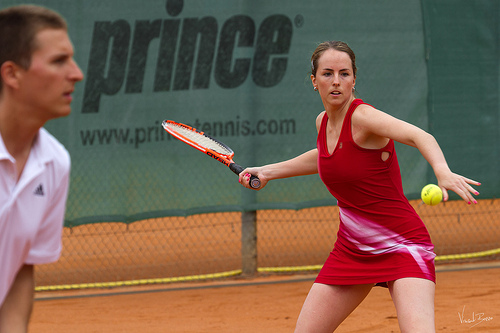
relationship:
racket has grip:
[161, 119, 260, 189] [229, 162, 260, 189]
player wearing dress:
[238, 42, 483, 333] [313, 99, 436, 286]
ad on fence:
[80, 0, 304, 144] [0, 1, 499, 228]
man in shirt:
[0, 4, 83, 332] [0, 127, 72, 308]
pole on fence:
[241, 211, 257, 279] [0, 1, 499, 228]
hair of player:
[311, 40, 357, 76] [238, 42, 483, 333]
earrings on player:
[313, 86, 318, 91] [238, 42, 483, 333]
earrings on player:
[352, 85, 355, 90] [238, 42, 483, 333]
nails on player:
[438, 180, 480, 204] [238, 42, 483, 333]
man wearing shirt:
[0, 4, 83, 332] [0, 127, 72, 308]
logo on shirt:
[34, 182, 46, 197] [0, 127, 72, 308]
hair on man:
[0, 5, 67, 69] [0, 4, 83, 332]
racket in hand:
[161, 119, 260, 189] [237, 166, 267, 189]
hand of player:
[237, 166, 267, 189] [238, 42, 483, 333]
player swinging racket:
[238, 42, 483, 333] [161, 119, 260, 189]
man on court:
[0, 4, 83, 332] [1, 200, 498, 333]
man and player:
[0, 4, 83, 332] [238, 42, 483, 333]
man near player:
[0, 4, 83, 332] [238, 42, 483, 333]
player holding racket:
[238, 42, 483, 333] [161, 119, 260, 189]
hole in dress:
[380, 149, 392, 164] [313, 99, 436, 286]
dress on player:
[313, 99, 436, 286] [238, 42, 483, 333]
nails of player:
[438, 180, 480, 204] [238, 42, 483, 333]